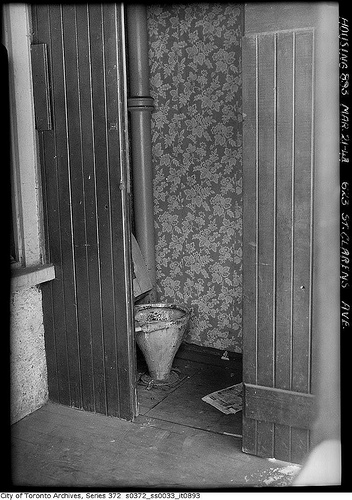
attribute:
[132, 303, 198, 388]
toilet — metal 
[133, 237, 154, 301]
lid — homemade 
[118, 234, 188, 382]
toilet — severely broken, back 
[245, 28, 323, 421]
surface — wood paneled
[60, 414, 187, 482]
surface — wooden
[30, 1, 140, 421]
door — wooden 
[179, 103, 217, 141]
flower — design 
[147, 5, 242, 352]
wallpaper — floral, bathroom's 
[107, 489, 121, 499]
label — archives  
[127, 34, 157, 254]
pipe — plumbing, metal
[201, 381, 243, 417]
newspaper — discarded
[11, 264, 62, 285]
window sill — window 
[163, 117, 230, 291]
pattern — floral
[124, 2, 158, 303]
pipe — plumbing 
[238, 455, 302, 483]
white paint — few flecks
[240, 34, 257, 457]
wooden plank — four wooden 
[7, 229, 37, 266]
corner — window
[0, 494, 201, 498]
serial identification — black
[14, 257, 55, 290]
surface — white wooden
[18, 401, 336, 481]
floor — wooden 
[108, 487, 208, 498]
number — label  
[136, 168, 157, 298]
water — flowage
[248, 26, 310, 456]
paneling — wood